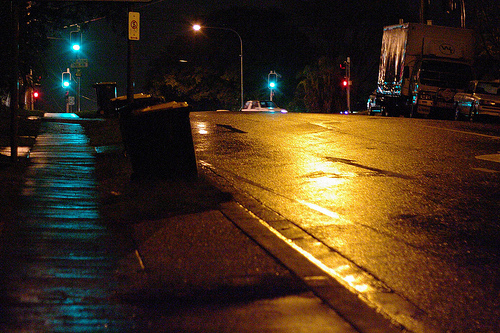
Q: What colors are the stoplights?
A: Red, green.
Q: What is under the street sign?
A: Trash cans.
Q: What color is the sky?
A: Black.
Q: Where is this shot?
A: Sidewalk.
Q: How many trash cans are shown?
A: 3.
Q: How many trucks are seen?
A: 1.